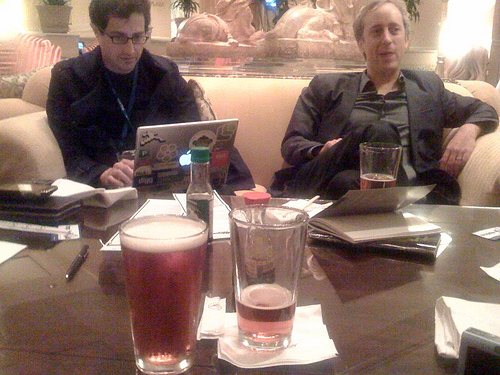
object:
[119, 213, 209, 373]
full glass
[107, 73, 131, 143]
blue lanyard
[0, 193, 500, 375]
table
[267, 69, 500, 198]
clothes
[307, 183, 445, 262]
books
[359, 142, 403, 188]
glass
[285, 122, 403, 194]
legs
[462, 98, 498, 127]
elbow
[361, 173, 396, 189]
drink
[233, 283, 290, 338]
drink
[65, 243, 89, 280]
pen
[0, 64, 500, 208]
couch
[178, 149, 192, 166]
apple icon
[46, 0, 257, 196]
man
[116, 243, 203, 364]
beverage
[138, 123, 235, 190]
stickers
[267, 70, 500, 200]
jacket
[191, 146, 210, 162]
green cap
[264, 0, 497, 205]
man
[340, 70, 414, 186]
shirt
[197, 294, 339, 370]
napkin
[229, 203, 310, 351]
glass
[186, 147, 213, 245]
condiment bottle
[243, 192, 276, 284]
condiment bottle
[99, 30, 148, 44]
eyeglasses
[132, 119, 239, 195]
laptop